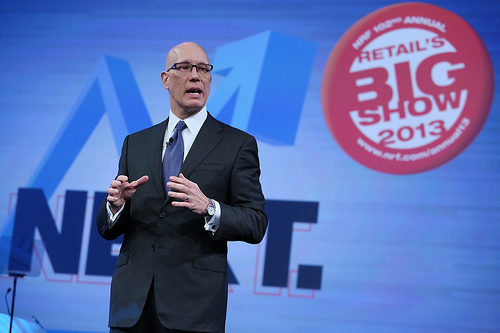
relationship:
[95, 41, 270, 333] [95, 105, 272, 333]
man wears suit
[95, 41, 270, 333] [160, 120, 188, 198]
man wears tie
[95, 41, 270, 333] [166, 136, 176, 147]
man wears microphone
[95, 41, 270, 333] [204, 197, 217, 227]
man wears watch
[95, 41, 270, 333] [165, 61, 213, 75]
man wears glasses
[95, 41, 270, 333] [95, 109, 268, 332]
man wears jacket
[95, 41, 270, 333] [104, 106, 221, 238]
man wears shirt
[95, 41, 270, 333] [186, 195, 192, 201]
man wears ring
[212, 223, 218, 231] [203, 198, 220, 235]
button on sleeve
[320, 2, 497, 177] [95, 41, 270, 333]
sign behind man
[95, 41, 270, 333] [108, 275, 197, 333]
man wears pants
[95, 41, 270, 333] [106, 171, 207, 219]
man has hands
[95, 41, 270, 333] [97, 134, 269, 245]
man has arms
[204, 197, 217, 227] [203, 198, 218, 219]
watch on wrist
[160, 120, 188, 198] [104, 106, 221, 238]
tie over shirt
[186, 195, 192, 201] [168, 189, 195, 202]
ring on finger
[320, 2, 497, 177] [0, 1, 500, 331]
sign on screen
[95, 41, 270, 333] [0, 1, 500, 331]
man standing in front of screen